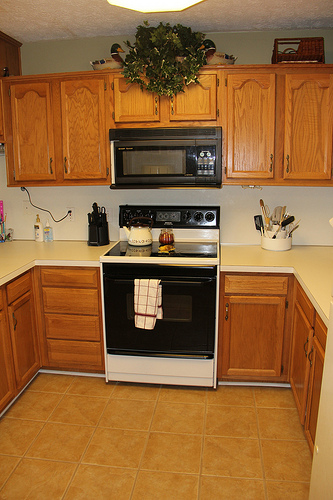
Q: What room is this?
A: The kitchen.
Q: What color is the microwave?
A: Black.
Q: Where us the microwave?
A: Hanging over the stove.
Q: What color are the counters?
A: White.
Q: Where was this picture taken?
A: In a kitchen.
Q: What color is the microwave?
A: Black.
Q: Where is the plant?
A: On top of the cabinets above the microwave.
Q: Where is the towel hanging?
A: On the oven door.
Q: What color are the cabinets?
A: Brown.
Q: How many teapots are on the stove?
A: One.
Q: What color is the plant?
A: Green.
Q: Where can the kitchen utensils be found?
A: On the countertop.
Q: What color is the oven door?
A: Black.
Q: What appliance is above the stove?
A: Microwave.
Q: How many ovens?
A: 1.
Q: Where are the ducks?
A: On top of the cabinets.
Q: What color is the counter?
A: White.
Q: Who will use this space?
A: People.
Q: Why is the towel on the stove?
A: To clean hands.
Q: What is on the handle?
A: Towel.